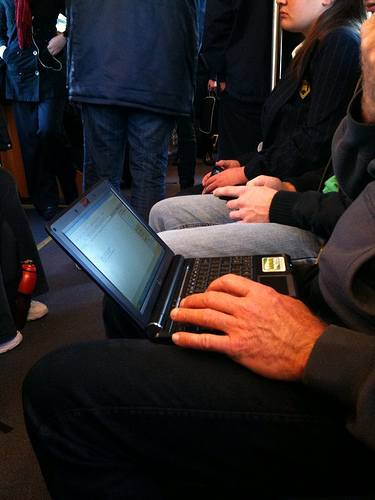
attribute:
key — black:
[218, 261, 229, 268]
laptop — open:
[44, 174, 296, 339]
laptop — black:
[41, 170, 321, 343]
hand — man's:
[164, 264, 329, 371]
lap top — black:
[43, 179, 299, 345]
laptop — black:
[39, 175, 300, 350]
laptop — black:
[49, 196, 307, 349]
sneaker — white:
[26, 300, 49, 319]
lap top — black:
[54, 180, 300, 336]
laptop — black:
[62, 168, 306, 283]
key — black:
[203, 265, 214, 275]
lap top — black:
[55, 180, 323, 339]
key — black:
[186, 248, 242, 303]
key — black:
[198, 278, 208, 280]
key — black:
[197, 272, 208, 280]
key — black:
[210, 268, 220, 274]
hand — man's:
[165, 265, 340, 386]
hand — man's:
[165, 268, 325, 386]